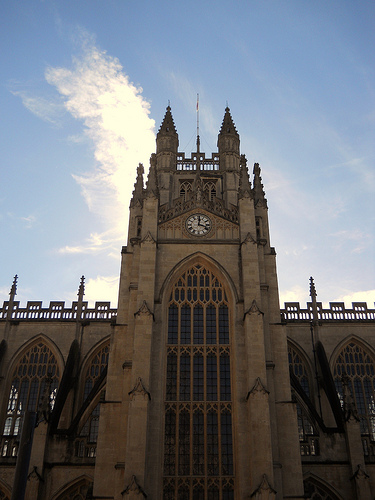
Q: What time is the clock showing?
A: 3.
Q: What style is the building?
A: Cathedral.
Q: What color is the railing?
A: Black.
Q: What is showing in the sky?
A: Clouds.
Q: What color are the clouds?
A: White.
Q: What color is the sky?
A: Blue.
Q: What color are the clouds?
A: White.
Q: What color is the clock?
A: White.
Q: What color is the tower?
A: Brown.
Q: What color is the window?
A: Black.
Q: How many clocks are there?
A: One.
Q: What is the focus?
A: Cathedral clock tower.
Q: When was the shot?
A: Daytime.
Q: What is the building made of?
A: Stone.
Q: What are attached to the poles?
A: Flags.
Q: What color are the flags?
A: Black.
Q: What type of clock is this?
A: Analog.